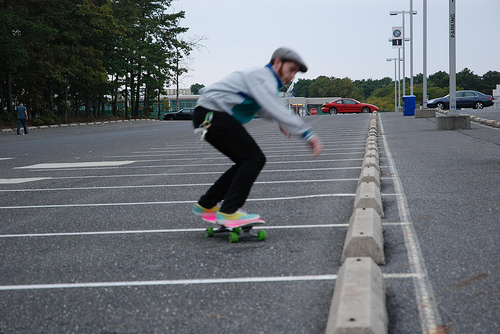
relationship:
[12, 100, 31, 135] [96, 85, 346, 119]
man on building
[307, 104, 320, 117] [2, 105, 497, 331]
sign on parking lot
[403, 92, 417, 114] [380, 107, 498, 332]
container on walkway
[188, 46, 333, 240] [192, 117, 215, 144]
man has keys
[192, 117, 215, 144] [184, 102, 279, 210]
keys on pants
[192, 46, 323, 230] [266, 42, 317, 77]
man wearing hat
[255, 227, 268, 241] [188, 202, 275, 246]
wheel on skateboard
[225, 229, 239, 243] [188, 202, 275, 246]
wheel on skateboard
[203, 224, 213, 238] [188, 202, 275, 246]
wheel on skateboard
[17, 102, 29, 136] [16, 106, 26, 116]
man wearing shirt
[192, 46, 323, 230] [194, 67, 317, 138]
man wearing gray sweatshirt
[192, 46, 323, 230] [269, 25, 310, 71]
man wearing hat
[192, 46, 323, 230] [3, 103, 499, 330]
man in lot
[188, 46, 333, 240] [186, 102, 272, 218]
man wearing pants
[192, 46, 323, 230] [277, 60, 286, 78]
man with burns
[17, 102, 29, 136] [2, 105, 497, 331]
man walking in parking lot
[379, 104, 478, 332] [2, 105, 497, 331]
walkway between parking lot